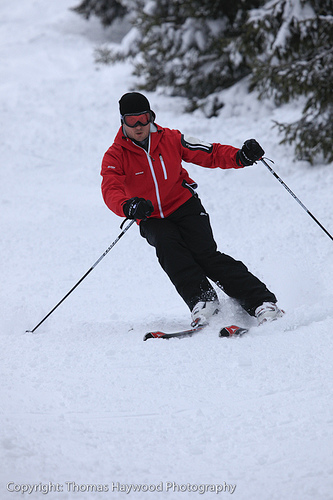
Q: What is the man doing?
A: Skiing.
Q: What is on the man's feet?
A: Skis.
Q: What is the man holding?
A: Poles.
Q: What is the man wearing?
A: A jacket and pants.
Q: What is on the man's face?
A: Goggles.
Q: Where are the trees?
A: Off to the side.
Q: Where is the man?
A: On a ski slope.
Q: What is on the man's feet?
A: Skis.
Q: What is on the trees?
A: Snow.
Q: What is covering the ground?
A: Snow.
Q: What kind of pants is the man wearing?
A: Snow pants.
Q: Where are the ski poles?
A: In the man's hands.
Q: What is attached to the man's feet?
A: Skis.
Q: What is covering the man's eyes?
A: Goggles.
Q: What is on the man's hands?
A: Gloves.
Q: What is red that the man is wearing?
A: A jacket.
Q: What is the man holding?
A: Ski poles.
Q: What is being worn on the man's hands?
A: Black gloves.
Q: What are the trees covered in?
A: Snow.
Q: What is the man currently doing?
A: Skiing.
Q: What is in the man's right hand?
A: Ski pole.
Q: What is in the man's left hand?
A: Ski pole.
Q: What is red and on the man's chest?
A: A jacket.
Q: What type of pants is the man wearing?
A: Black pants.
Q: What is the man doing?
A: Skiing downhill.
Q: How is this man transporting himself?
A: Skiing.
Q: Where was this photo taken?
A: On a ski slope.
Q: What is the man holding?
A: Ski poles.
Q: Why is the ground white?
A: Covered in snow.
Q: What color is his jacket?
A: Red.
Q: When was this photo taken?
A: During the day.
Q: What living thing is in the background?
A: A tree.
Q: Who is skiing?
A: A man.